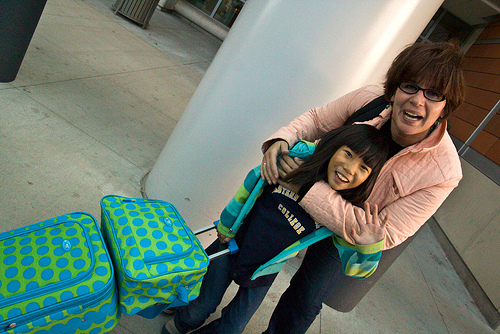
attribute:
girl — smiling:
[264, 106, 378, 292]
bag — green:
[107, 176, 218, 327]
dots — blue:
[139, 225, 165, 255]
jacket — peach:
[376, 127, 464, 272]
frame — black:
[410, 86, 444, 97]